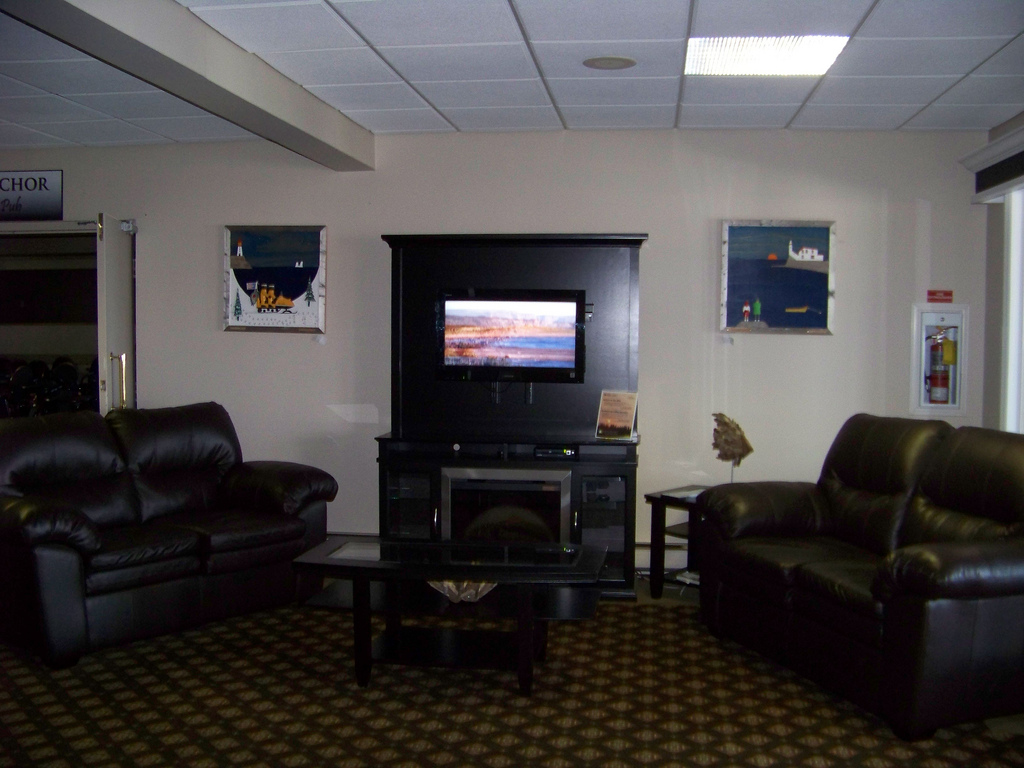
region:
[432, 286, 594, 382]
Tv in a living room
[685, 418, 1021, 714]
Brown sofa in a living room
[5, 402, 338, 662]
Black sofa in a living room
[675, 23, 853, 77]
Light on the ceiling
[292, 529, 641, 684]
Table in the living room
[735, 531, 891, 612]
Cushions on a sofa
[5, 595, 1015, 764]
Carpet on the floor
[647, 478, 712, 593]
A table next to a sofa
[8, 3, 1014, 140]
A ceiling in a living room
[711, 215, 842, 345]
A picture on a wall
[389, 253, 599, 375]
the tv is on the wall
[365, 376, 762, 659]
the fireplace is black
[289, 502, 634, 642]
this is a coffee table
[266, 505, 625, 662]
the table is glass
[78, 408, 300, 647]
this is a couch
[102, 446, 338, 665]
the couch is black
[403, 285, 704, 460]
the tv is on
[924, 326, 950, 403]
the fire extinguisher is red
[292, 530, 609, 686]
the coffee table is black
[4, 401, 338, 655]
the couch is black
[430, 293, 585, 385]
the black tv is turned on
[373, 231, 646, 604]
the tv in the black entertainment center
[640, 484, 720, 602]
the end table is black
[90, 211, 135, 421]
the door is white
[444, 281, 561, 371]
the television is on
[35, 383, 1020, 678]
two sofas in the room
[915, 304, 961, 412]
a fire hydrant on the wall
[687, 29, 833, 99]
a ceiling light is on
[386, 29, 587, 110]
white tiles on the ceiling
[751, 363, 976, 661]
the sofa is made of leather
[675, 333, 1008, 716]
the sofa is brown in color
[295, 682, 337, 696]
pattern on the floor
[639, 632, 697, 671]
pattern on the floor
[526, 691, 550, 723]
pattern on the floor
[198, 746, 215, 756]
pattern on the floor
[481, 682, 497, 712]
pattern on the floor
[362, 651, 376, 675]
pattern on the floor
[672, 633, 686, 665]
pattern on the floor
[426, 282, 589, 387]
A black flatscreen tv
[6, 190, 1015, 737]
A living room with two leather couches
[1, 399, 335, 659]
A dark colored leather couch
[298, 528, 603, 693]
A dark colored wooden coffee table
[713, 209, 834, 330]
A painting hanging on the wall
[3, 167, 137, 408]
An open door with a sign overhead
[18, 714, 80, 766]
a brown and yellow diamond design on a carpet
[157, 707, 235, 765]
a brown and yellow diamond design on a carpet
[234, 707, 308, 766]
a brown and yellow diamond design on a carpet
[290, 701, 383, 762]
a brown and yellow diamond design on a carpet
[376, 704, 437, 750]
a brown and yellow diamond design on a carpet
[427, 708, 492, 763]
a brown and yellow diamond design on a carpet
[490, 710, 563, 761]
a brown and yellow diamond design on a carpet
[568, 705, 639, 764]
a brown and yellow diamond design on a carpet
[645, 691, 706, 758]
a brown and yellow diamond design on a carpet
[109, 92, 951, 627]
this is a living room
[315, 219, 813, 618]
this is a fire place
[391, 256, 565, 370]
this is a tv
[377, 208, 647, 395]
the tv is on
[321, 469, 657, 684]
this is a coffee table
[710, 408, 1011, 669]
the couch is leather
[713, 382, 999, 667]
the couch is brown